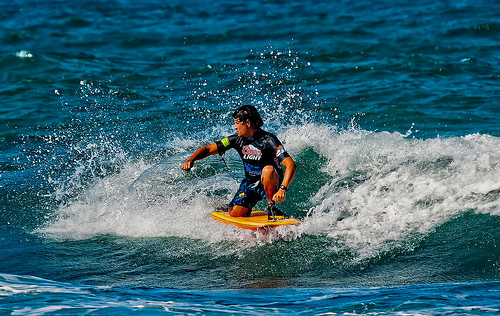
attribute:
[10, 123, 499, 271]
wave — white, white topped, white crested, foamy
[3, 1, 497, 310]
sea — blue, splashing over surfe, choppy, clear, crystal blue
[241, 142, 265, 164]
coors light logo — white, red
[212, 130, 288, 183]
shirt — blue, short sleeved, mostly black, black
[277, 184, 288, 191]
watch — black, waterproof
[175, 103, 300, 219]
surfer — tan, doing a sport, left facing, lone, male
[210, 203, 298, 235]
surfboard — yellow, bright orange, orange, dark yellow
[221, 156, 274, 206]
surfer leash — blue coiled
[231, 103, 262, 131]
hair — dark, black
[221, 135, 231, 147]
pad — striped, green